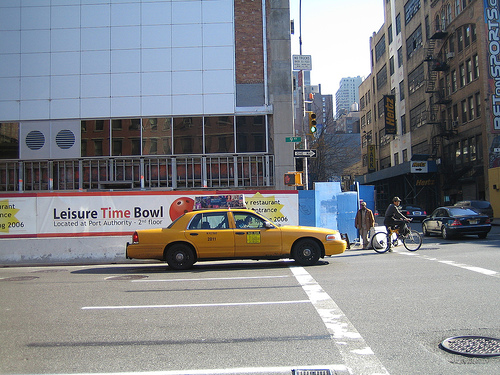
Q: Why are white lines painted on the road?
A: To ease driving.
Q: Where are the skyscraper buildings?
A: Behind the yellow cab.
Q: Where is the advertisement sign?
A: On a city street.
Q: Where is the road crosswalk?
A: On a city street.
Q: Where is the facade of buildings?
A: On a city street.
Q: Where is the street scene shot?
A: In a city.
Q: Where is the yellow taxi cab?
A: On a city street.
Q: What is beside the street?
A: A facade of buildings.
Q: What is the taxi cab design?
A: Yellow sedan.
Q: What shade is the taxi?
A: Yellow.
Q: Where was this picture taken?
A: A city.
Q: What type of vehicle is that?
A: Taxi cab.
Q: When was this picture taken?
A: Daytime.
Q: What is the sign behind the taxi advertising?
A: Bowling alley.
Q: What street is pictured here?
A: 9th Street.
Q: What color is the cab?
A: Yellow.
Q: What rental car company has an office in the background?
A: Hertz.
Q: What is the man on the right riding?
A: Bicycle.